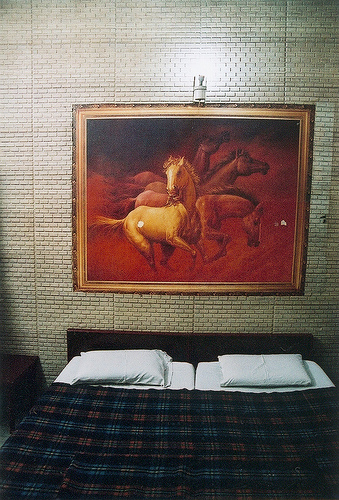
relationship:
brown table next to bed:
[1, 350, 44, 434] [0, 324, 338, 499]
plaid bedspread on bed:
[1, 384, 337, 498] [0, 324, 338, 499]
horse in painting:
[85, 155, 210, 276] [70, 101, 314, 296]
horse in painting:
[130, 152, 268, 200] [70, 101, 314, 296]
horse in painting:
[163, 186, 265, 265] [70, 101, 314, 296]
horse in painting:
[97, 157, 214, 271] [70, 101, 314, 296]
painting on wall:
[70, 101, 314, 296] [3, 1, 337, 384]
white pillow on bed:
[216, 349, 312, 388] [0, 324, 338, 499]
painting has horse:
[70, 101, 314, 296] [85, 155, 210, 276]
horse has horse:
[85, 155, 210, 276] [99, 183, 266, 265]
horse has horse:
[85, 155, 210, 276] [99, 145, 268, 201]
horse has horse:
[85, 155, 210, 276] [99, 131, 232, 188]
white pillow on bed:
[72, 349, 171, 387] [0, 324, 338, 499]